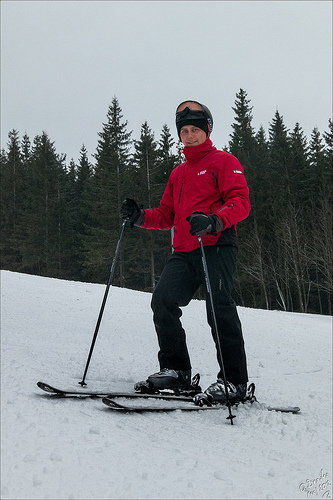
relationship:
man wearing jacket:
[116, 97, 259, 400] [139, 138, 251, 252]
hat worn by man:
[176, 101, 211, 137] [119, 100, 250, 401]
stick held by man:
[80, 214, 130, 386] [119, 100, 250, 401]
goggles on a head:
[172, 99, 205, 115] [171, 98, 212, 146]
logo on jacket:
[197, 166, 206, 175] [139, 138, 251, 252]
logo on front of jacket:
[198, 169, 207, 176] [140, 137, 251, 251]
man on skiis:
[119, 100, 250, 401] [77, 373, 301, 442]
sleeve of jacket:
[215, 154, 250, 230] [133, 142, 253, 254]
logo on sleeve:
[233, 166, 242, 174] [215, 154, 250, 230]